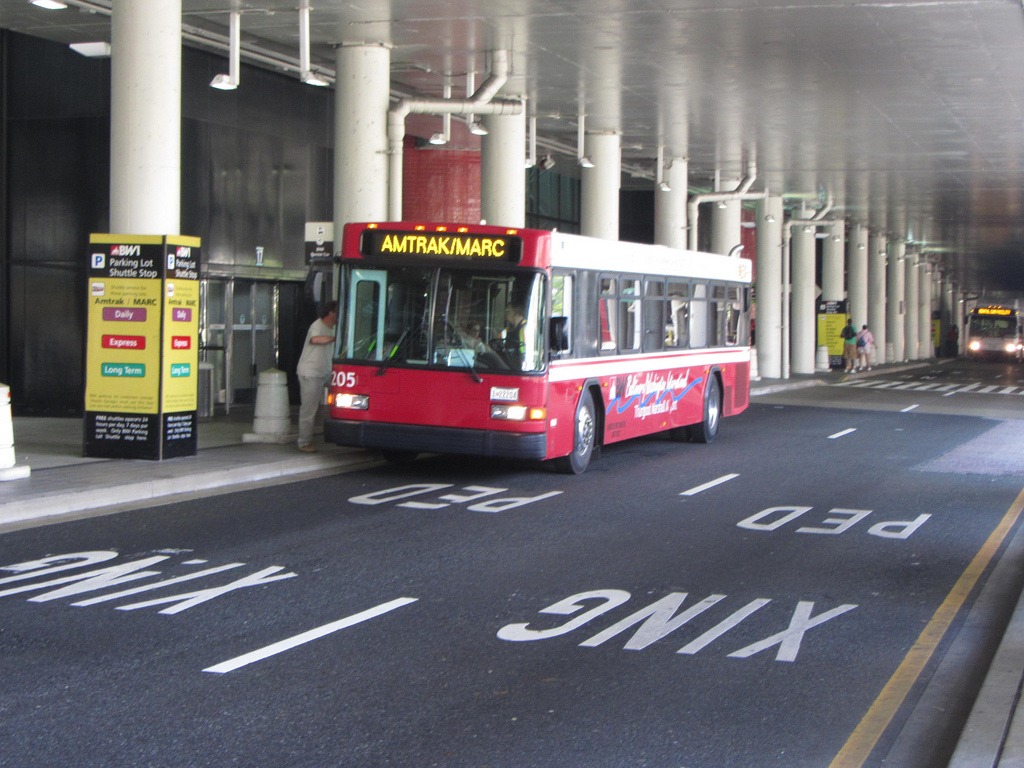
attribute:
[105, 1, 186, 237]
column — white 